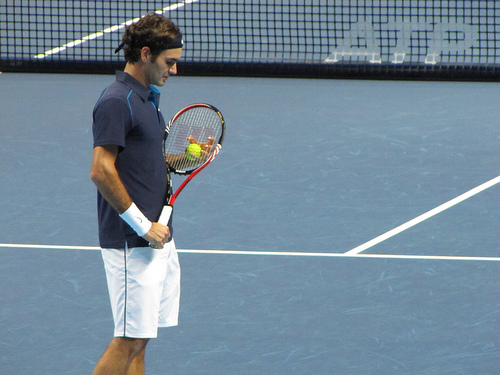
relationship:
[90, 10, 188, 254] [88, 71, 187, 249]
man wearing shirt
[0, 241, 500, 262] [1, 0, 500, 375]
line on court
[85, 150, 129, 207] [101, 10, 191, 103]
arm on person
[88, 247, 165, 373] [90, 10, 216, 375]
leg on man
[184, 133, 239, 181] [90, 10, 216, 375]
hand on man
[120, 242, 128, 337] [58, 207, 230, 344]
stripe on shorts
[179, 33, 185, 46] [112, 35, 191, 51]
design on headband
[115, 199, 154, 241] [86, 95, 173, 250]
band on arm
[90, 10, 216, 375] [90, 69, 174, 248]
man wearing polo shirt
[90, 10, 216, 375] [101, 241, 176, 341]
man wearing white shorts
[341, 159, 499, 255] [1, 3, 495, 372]
lines on court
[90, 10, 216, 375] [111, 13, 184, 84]
man on head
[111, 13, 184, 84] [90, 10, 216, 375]
head of man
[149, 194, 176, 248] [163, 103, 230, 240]
handle of racket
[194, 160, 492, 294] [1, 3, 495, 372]
lines of court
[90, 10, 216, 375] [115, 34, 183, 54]
man wearing fabric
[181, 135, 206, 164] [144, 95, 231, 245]
ball on tennis racket